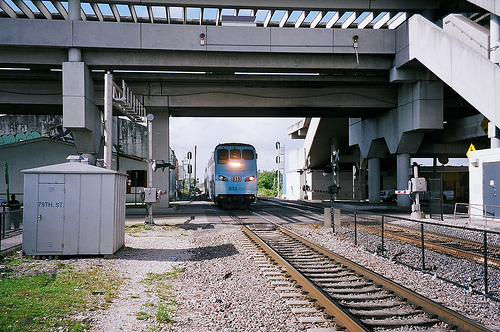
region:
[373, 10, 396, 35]
silver metal ceiling beam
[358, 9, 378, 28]
silver metal ceiling beam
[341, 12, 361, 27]
silver metal ceiling beam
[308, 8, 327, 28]
silver metal ceiling beam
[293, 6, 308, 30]
silver metal ceiling beam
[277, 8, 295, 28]
silver metal ceiling beam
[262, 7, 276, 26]
silver metal ceiling beam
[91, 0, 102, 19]
silver metal ceiling beam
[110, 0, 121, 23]
silver metal ceiling beam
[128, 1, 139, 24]
silver metal ceiling beam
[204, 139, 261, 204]
a blue colored train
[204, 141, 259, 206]
a train with three illuminated lights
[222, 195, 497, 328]
two sets of train tracks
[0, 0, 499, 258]
train going under a bridge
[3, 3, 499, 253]
a concrete bridge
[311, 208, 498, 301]
a metal fence separating the tracks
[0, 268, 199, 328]
grass growing in the gravels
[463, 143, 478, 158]
a diamond shape yellow sign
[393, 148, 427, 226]
This is a pillar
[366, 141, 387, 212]
This is a pillar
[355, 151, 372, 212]
This is a pillar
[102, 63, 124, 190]
This is a pillar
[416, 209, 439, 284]
This is a pole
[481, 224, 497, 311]
This is a pole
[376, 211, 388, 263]
This is a pole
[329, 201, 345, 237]
This is a pole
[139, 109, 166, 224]
This is a pole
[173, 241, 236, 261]
a shadow on the ground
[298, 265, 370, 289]
the train tracks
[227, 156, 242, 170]
a light on the train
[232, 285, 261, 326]
small rocks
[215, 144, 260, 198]
the train is blue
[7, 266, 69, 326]
a small patch of grass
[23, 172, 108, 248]
a small shed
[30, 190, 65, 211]
writing on the shed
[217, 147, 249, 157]
the windshield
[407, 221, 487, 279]
a small fence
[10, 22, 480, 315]
The train is on the railroad tracks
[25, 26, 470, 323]
The train is going through a city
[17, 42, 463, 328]
The train is bringing many passengers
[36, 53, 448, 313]
The train has its lights on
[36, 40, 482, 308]
The train has a powerful motor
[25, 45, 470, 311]
The train is close to the terminal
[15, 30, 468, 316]
The train belongs to a company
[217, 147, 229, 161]
glass window on train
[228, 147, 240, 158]
glass window on train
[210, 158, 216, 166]
glass window on train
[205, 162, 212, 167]
glass window on train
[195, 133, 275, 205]
The incoming train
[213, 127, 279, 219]
A incoming train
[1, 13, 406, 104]
The metal bridge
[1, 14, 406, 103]
A metal bridge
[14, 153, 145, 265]
The large electrical box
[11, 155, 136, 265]
A large electrical box on the floor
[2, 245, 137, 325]
The green patch on the floor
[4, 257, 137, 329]
A green patch on the floor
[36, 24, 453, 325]
this is a train station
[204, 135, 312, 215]
this is a train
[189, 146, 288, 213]
the headlight is bright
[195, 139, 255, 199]
the headlight is yellow